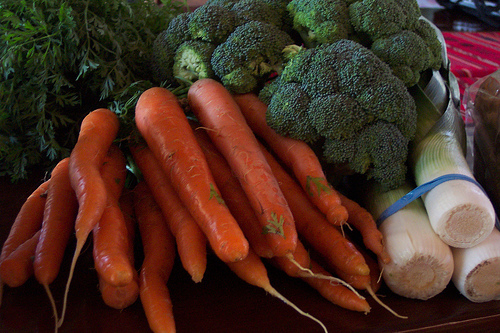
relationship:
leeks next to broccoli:
[355, 17, 500, 303] [150, 0, 445, 193]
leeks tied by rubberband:
[355, 17, 500, 303] [375, 172, 499, 230]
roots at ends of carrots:
[43, 220, 410, 332] [2, 75, 407, 331]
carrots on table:
[2, 75, 407, 331] [1, 2, 500, 331]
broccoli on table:
[150, 0, 445, 193] [1, 2, 500, 331]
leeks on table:
[355, 17, 500, 303] [1, 2, 500, 331]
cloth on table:
[431, 30, 499, 126] [1, 2, 500, 331]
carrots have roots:
[2, 75, 407, 331] [43, 220, 410, 332]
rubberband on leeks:
[375, 172, 499, 230] [355, 17, 500, 303]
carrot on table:
[2, 178, 51, 286] [1, 2, 500, 331]